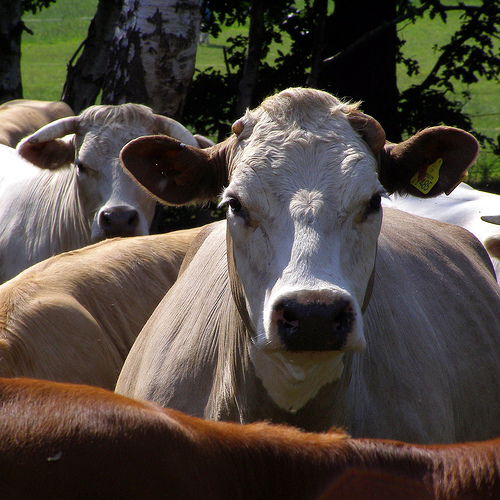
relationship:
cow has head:
[114, 87, 495, 440] [215, 86, 386, 383]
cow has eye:
[114, 87, 495, 440] [218, 189, 249, 227]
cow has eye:
[114, 87, 495, 440] [365, 190, 384, 212]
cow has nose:
[114, 87, 495, 440] [274, 291, 356, 351]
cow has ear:
[114, 87, 495, 440] [119, 134, 229, 207]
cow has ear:
[114, 87, 495, 440] [390, 125, 480, 199]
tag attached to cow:
[409, 158, 443, 196] [114, 87, 495, 440]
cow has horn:
[114, 87, 495, 440] [230, 119, 256, 139]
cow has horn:
[114, 87, 495, 440] [345, 108, 386, 153]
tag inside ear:
[409, 158, 443, 196] [390, 125, 480, 199]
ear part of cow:
[390, 125, 480, 199] [114, 87, 495, 440]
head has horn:
[215, 86, 386, 383] [345, 108, 386, 153]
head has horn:
[215, 86, 386, 383] [230, 119, 256, 139]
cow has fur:
[114, 87, 495, 440] [124, 88, 493, 433]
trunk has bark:
[64, 4, 203, 124] [110, 3, 197, 115]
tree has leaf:
[264, 7, 496, 142] [407, 65, 416, 78]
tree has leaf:
[264, 7, 496, 142] [443, 77, 455, 94]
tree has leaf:
[264, 7, 496, 142] [477, 32, 492, 47]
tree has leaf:
[264, 7, 496, 142] [486, 133, 496, 152]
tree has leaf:
[264, 7, 496, 142] [436, 11, 449, 23]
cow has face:
[114, 87, 495, 440] [225, 186, 383, 352]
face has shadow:
[225, 186, 383, 352] [231, 189, 296, 341]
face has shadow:
[225, 186, 383, 352] [339, 220, 378, 304]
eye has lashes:
[218, 189, 249, 227] [215, 194, 237, 211]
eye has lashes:
[365, 190, 384, 212] [371, 186, 393, 203]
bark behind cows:
[110, 3, 197, 115] [5, 87, 493, 486]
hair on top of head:
[242, 85, 364, 131] [215, 86, 386, 383]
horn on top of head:
[230, 119, 256, 139] [215, 86, 386, 383]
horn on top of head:
[345, 108, 386, 153] [215, 86, 386, 383]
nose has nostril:
[274, 291, 356, 351] [277, 304, 300, 330]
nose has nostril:
[274, 291, 356, 351] [326, 304, 349, 330]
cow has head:
[6, 105, 216, 280] [73, 106, 160, 246]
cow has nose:
[6, 105, 216, 280] [100, 205, 141, 234]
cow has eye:
[6, 105, 216, 280] [75, 159, 95, 179]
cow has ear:
[6, 105, 216, 280] [16, 137, 76, 171]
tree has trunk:
[264, 7, 496, 142] [311, 6, 400, 144]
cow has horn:
[6, 105, 216, 280] [16, 116, 83, 156]